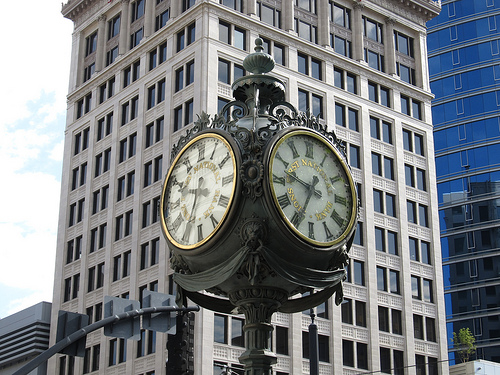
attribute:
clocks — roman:
[125, 136, 383, 250]